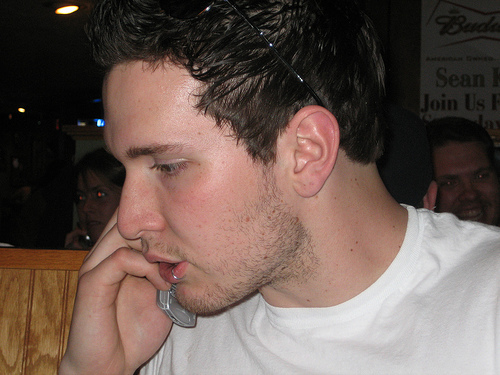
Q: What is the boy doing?
A: Talking on the phone.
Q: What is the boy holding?
A: A cellphone.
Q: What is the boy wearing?
A: A white t shirt.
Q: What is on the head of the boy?
A: Glasses.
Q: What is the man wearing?
A: White shirt.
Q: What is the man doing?
A: Talking on the phone.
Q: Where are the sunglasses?
A: On the man head.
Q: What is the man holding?
A: Cell phone.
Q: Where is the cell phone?
A: In the man's hand.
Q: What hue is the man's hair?
A: Black.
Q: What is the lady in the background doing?
A: On the phone.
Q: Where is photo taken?
A: In restaurant.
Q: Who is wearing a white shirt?
A: The man.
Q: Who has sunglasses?
A: The man.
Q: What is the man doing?
A: Talking on cellphone.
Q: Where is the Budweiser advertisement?
A: In back.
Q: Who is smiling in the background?
A: The man.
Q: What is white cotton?
A: Shirt.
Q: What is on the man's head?
A: Freckles.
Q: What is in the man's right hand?
A: Phone.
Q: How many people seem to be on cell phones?
A: 2.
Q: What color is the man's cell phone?
A: Silver.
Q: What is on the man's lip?
A: A piercing.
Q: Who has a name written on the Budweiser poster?
A: Sean.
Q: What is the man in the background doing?
A: Smiling.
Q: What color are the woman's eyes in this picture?
A: Red.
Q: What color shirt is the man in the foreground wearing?
A: White.